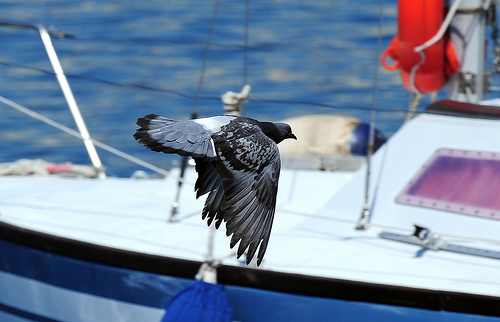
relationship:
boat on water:
[1, 0, 500, 321] [0, 0, 499, 176]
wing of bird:
[214, 129, 280, 267] [135, 113, 298, 267]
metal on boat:
[1, 23, 109, 180] [1, 0, 500, 321]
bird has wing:
[135, 113, 298, 267] [213, 133, 281, 267]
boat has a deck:
[1, 0, 500, 321] [1, 98, 499, 296]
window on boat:
[395, 147, 499, 224] [1, 0, 500, 321]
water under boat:
[0, 0, 499, 176] [1, 0, 500, 321]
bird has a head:
[135, 113, 298, 267] [276, 122, 298, 141]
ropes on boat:
[1, 0, 499, 230] [1, 0, 500, 321]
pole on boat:
[445, 0, 491, 102] [1, 0, 500, 321]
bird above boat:
[135, 113, 298, 267] [1, 0, 500, 321]